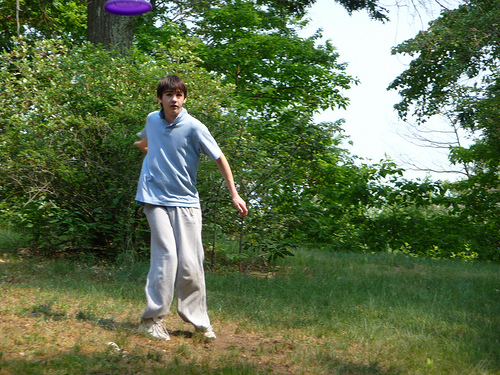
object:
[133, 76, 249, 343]
boy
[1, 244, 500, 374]
field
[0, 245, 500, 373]
grass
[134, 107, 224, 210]
t-shirt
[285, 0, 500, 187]
clouds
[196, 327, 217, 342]
shoes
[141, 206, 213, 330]
pants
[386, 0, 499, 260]
tree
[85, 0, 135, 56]
trunk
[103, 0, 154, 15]
frisbee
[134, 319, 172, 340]
shoe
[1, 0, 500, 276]
bush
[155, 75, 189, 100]
hair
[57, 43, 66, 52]
flower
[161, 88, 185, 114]
face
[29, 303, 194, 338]
shadow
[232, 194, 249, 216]
hand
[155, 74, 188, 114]
head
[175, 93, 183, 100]
eye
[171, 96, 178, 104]
nose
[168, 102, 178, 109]
mouth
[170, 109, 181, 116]
chin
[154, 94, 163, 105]
ear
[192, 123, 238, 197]
arm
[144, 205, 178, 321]
leg